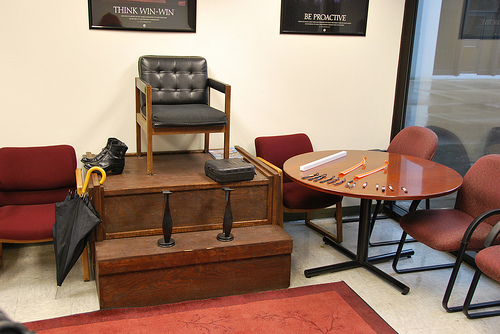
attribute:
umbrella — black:
[32, 163, 120, 305]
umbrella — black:
[52, 165, 106, 300]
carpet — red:
[0, 277, 399, 330]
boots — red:
[80, 137, 130, 178]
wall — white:
[230, 38, 439, 166]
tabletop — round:
[278, 132, 487, 322]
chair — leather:
[133, 52, 233, 174]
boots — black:
[76, 133, 134, 180]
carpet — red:
[12, 279, 429, 332]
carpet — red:
[239, 0, 320, 37]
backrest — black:
[133, 55, 213, 100]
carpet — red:
[4, 274, 411, 332]